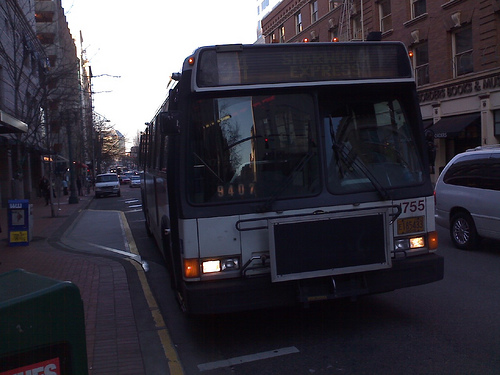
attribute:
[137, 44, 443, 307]
bus — white, big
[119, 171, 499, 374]
street — tar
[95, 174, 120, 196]
van — white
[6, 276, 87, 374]
bin — green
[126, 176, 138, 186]
car — white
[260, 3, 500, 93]
building — red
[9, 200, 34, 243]
newspaper dispenser — blue